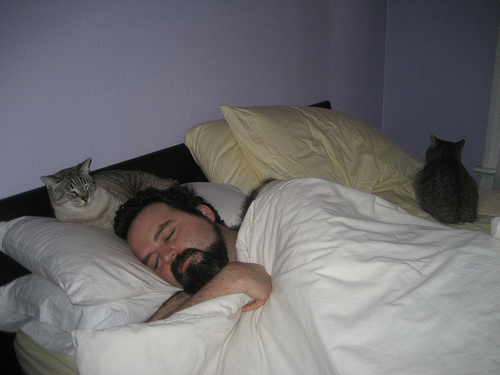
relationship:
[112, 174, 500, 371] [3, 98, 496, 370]
man sleeping in bed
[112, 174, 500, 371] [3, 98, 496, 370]
man in bed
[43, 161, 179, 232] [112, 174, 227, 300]
cat above head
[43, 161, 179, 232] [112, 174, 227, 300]
cat sleeping above head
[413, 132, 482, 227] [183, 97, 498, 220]
cat laying on sheets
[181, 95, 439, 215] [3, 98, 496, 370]
pillows on bed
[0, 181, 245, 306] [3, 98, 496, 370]
pillow on bed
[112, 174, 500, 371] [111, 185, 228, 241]
man with hair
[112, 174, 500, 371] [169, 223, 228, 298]
man with beard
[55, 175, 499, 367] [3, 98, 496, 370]
bed-cover on bed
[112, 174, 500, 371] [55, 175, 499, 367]
man holding bed-cover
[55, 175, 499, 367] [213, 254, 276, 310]
bed-cover with hand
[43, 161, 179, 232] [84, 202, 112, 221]
cat with belly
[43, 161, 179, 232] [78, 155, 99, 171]
cat has ear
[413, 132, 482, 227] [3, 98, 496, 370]
cat laying on bed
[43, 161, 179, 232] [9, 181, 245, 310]
cat laying on pillow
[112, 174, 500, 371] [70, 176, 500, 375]
man under bed-cover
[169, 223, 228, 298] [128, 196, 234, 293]
beard on face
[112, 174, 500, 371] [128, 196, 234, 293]
man has face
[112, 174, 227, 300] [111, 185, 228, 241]
head has hair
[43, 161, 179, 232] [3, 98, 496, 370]
cat laying on bed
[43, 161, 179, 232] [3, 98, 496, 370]
cat on bed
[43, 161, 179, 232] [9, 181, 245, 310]
cat on pillow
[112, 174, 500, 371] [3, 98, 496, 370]
man asleep in bed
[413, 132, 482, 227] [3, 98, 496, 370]
cat on bed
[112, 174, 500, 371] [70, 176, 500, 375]
man laying under bed-cover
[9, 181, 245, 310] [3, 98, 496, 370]
pillow on bed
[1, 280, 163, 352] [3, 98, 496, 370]
pillow on bed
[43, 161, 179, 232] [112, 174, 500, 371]
cat next to man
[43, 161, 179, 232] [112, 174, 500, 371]
cat laying next to man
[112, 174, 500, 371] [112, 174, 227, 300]
man has head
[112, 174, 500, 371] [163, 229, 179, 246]
man has eye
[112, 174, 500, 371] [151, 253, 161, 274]
man has eye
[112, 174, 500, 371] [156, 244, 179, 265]
man has nose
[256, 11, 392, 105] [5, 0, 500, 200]
shadows on wall